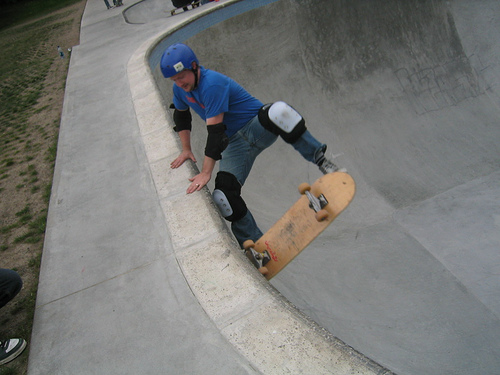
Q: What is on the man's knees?
A: Pads.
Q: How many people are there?
A: One.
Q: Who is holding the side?
A: Skater.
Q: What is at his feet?
A: Skateboard.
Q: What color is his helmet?
A: Blue.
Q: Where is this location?
A: Skatepark.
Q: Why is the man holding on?
A: To not fall.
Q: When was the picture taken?
A: Daytime.